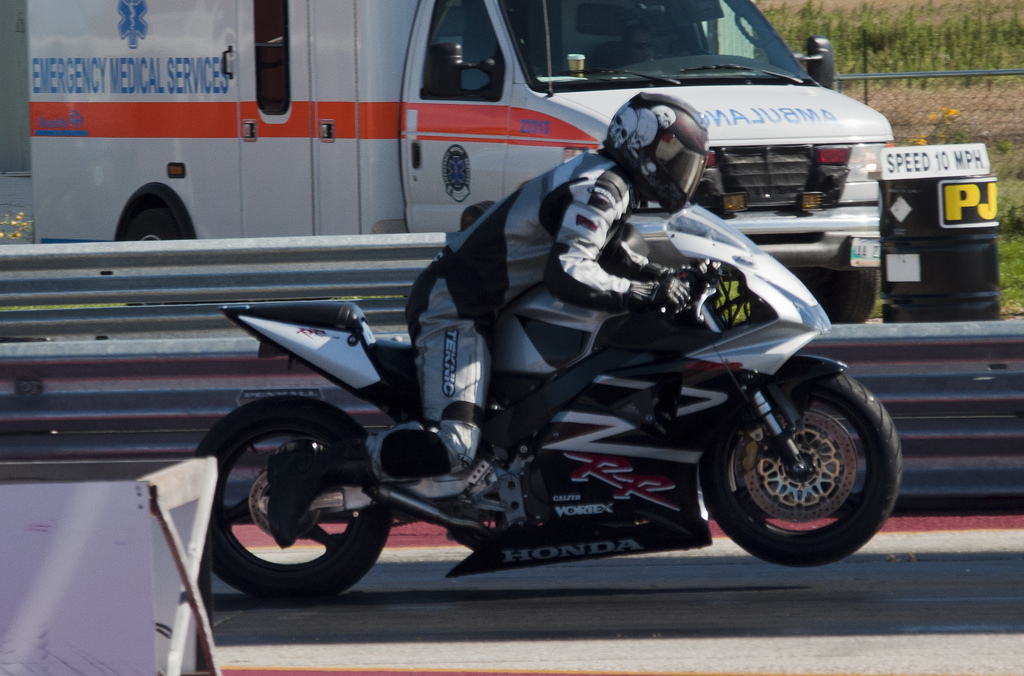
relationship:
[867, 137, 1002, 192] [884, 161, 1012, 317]
signs on a barrel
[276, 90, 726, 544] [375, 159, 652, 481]
man wearing jumpsuit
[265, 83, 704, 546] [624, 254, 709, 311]
racer wearing gloves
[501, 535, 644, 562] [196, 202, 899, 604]
word on bike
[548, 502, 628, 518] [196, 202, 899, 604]
word on bike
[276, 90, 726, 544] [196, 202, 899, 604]
man riding bike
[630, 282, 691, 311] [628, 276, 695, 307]
hand in glove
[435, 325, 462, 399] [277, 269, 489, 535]
logo on pants